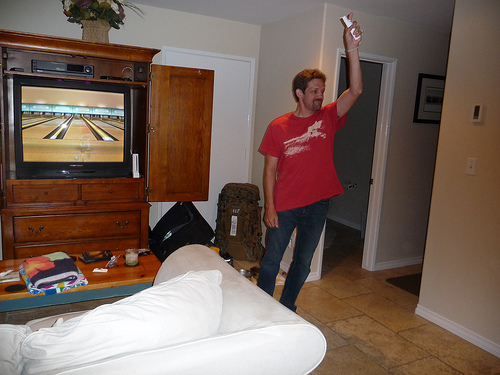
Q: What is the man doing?
A: Playing a game.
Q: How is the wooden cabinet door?
A: Open.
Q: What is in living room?
A: Flat screen tv.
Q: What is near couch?
A: A wooden coffee table.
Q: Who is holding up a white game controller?
A: A man.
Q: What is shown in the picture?
A: Brown wood entertainment center.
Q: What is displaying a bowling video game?
A: A tv.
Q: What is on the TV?
A: A bowling game.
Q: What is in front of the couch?
A: A wood table.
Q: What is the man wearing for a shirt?
A: A red Tee shirt.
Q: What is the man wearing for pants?
A: Jeans.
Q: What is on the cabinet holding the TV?
A: A plant in a pot.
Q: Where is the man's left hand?
A: In the air.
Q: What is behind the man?
A: A red backpack.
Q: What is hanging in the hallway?
A: A picture frame.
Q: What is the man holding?
A: A controller.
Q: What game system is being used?
A: Wii.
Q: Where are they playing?
A: In the living room.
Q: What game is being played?
A: Bowling.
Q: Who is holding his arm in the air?
A: The man.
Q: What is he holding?
A: A controller.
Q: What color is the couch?
A: White.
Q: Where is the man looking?
A: Away from the TV.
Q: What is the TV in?
A: An armoire.